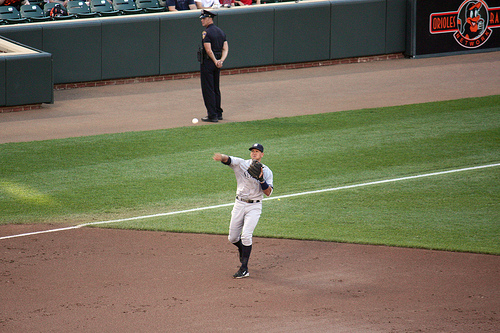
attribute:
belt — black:
[231, 193, 303, 218]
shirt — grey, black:
[223, 153, 275, 202]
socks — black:
[229, 240, 254, 270]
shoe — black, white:
[231, 262, 256, 282]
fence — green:
[0, 2, 498, 109]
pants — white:
[222, 194, 267, 249]